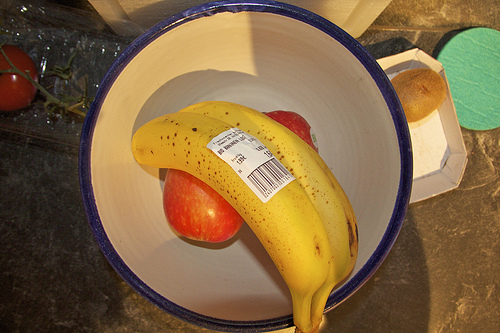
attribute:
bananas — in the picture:
[138, 100, 364, 330]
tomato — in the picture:
[2, 43, 39, 114]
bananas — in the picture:
[120, 75, 399, 307]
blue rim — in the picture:
[381, 85, 415, 252]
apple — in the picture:
[123, 108, 310, 273]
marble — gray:
[414, 208, 498, 331]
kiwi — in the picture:
[400, 70, 445, 122]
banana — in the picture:
[130, 110, 331, 331]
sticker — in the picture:
[207, 126, 295, 202]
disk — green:
[435, 25, 499, 132]